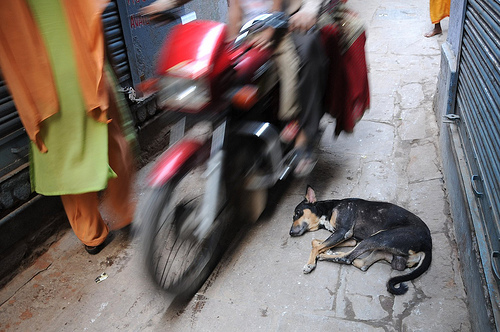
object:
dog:
[289, 184, 433, 295]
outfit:
[0, 0, 133, 248]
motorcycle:
[130, 7, 368, 298]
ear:
[305, 184, 316, 204]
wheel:
[135, 155, 231, 298]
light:
[156, 76, 209, 109]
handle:
[280, 23, 315, 34]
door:
[447, 0, 498, 331]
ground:
[0, 1, 468, 332]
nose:
[290, 230, 293, 234]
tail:
[386, 248, 433, 294]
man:
[131, 0, 326, 174]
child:
[223, 0, 301, 144]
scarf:
[0, 0, 114, 153]